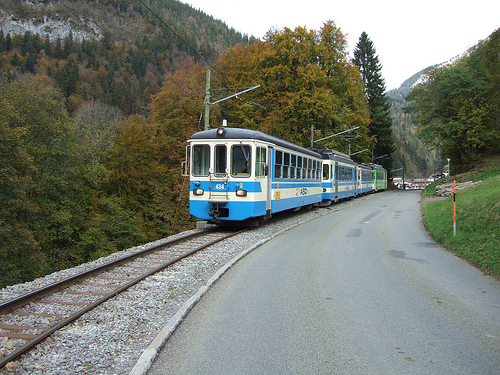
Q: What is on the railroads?
A: A blue and white train.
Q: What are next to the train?
A: Trees.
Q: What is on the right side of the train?
A: A street.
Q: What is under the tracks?
A: Rocks.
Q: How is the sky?
A: White.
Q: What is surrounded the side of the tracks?
A: Trees.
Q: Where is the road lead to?
A: Town.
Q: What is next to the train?
A: Some metal poles.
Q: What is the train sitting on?
A: A track.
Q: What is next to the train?
A: Some leafy trees.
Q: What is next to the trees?
A: A mountain.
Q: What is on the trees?
A: Colorful leaves.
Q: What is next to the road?
A: Green grass.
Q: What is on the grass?
A: An orange pole.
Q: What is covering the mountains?
A: Trees.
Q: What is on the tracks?
A: A train.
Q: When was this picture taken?
A: During the day.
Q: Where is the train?
A: In the mountains.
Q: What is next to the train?
A: A road.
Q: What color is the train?
A: Blue and white.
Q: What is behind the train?
A: Trees.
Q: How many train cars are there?
A: Four.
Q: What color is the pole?
A: Orange.